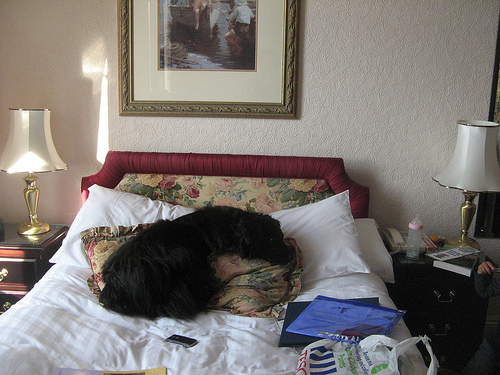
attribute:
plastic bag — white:
[298, 332, 441, 373]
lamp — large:
[2, 88, 77, 240]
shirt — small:
[284, 292, 405, 347]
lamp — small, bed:
[430, 112, 497, 234]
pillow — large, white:
[217, 187, 377, 284]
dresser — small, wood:
[387, 239, 494, 364]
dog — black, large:
[95, 202, 292, 322]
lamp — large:
[1, 105, 71, 235]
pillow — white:
[50, 181, 146, 237]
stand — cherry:
[387, 242, 489, 360]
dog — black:
[105, 202, 298, 319]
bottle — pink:
[393, 201, 430, 252]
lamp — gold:
[429, 115, 499, 255]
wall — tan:
[5, 3, 497, 229]